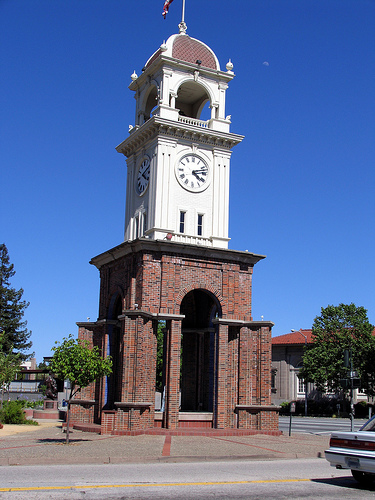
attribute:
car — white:
[324, 415, 374, 488]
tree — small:
[36, 333, 115, 446]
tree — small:
[297, 302, 374, 417]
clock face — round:
[172, 151, 214, 192]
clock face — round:
[131, 153, 152, 194]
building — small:
[270, 328, 368, 418]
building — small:
[7, 353, 37, 387]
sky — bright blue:
[0, 0, 374, 367]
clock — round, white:
[171, 149, 211, 196]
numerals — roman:
[179, 153, 204, 167]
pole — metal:
[176, 1, 192, 22]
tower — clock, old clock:
[65, 3, 292, 440]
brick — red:
[204, 269, 238, 288]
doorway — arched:
[172, 284, 230, 419]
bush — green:
[48, 334, 113, 443]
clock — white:
[176, 152, 211, 193]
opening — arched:
[179, 288, 221, 414]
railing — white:
[178, 117, 210, 126]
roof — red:
[272, 328, 360, 345]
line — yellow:
[4, 476, 351, 489]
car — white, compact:
[325, 415, 363, 474]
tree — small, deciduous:
[44, 332, 110, 444]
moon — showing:
[260, 58, 270, 68]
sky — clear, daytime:
[239, 8, 362, 252]